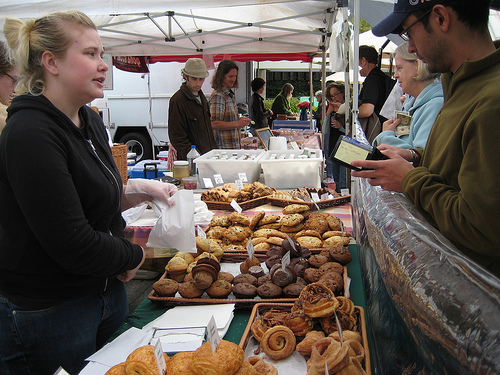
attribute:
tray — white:
[148, 250, 348, 303]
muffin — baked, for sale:
[192, 263, 218, 286]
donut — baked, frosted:
[262, 327, 296, 361]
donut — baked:
[305, 339, 350, 371]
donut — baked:
[251, 315, 281, 340]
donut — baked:
[282, 310, 313, 336]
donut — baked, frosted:
[301, 292, 338, 319]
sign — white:
[101, 53, 114, 93]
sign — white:
[204, 178, 215, 190]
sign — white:
[212, 175, 224, 185]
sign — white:
[237, 171, 248, 182]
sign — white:
[234, 178, 245, 191]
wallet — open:
[329, 133, 390, 179]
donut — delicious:
[262, 309, 290, 322]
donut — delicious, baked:
[338, 295, 355, 317]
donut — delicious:
[298, 282, 333, 299]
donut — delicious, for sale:
[322, 310, 357, 335]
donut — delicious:
[329, 329, 362, 342]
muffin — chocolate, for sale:
[233, 283, 256, 298]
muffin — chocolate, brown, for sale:
[259, 283, 282, 298]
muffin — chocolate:
[248, 264, 264, 277]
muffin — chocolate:
[257, 272, 273, 285]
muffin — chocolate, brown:
[271, 264, 297, 287]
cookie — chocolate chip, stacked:
[224, 226, 247, 243]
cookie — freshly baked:
[248, 212, 263, 230]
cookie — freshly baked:
[256, 213, 280, 226]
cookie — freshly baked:
[257, 222, 283, 230]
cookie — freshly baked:
[249, 228, 278, 237]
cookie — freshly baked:
[249, 236, 267, 245]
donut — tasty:
[297, 329, 324, 350]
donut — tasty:
[343, 338, 364, 359]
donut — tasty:
[342, 357, 365, 374]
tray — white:
[237, 300, 373, 375]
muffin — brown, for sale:
[291, 257, 307, 276]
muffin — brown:
[284, 279, 307, 296]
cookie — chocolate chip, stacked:
[281, 202, 309, 215]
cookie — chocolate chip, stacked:
[279, 214, 304, 227]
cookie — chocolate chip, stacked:
[279, 224, 304, 232]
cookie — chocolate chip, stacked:
[293, 229, 323, 239]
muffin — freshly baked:
[308, 252, 328, 266]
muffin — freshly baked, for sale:
[329, 243, 353, 264]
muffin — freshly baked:
[319, 247, 334, 260]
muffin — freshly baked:
[319, 260, 343, 276]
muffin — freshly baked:
[303, 266, 322, 282]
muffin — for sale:
[320, 271, 348, 285]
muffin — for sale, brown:
[319, 278, 341, 294]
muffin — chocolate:
[195, 255, 223, 270]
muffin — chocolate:
[295, 275, 308, 286]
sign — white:
[229, 198, 243, 212]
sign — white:
[341, 187, 350, 198]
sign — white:
[321, 192, 330, 203]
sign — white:
[310, 192, 321, 204]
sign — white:
[245, 239, 256, 260]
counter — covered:
[78, 235, 376, 373]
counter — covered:
[239, 125, 326, 174]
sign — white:
[259, 259, 272, 275]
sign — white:
[278, 249, 292, 269]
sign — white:
[196, 223, 211, 240]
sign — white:
[338, 219, 347, 237]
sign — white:
[206, 315, 223, 352]